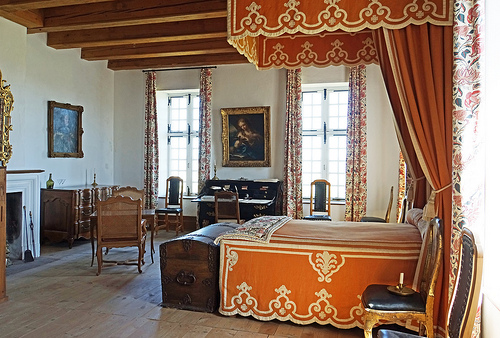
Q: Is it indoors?
A: Yes, it is indoors.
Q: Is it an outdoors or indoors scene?
A: It is indoors.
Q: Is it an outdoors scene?
A: No, it is indoors.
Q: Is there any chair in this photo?
A: Yes, there is a chair.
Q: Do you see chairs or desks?
A: Yes, there is a chair.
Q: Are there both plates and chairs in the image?
A: No, there is a chair but no plates.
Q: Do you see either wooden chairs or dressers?
A: Yes, there is a wood chair.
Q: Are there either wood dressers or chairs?
A: Yes, there is a wood chair.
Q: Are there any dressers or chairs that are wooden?
A: Yes, the chair is wooden.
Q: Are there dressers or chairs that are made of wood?
A: Yes, the chair is made of wood.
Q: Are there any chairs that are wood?
A: Yes, there is a wood chair.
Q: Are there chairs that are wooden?
A: Yes, there is a chair that is wooden.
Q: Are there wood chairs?
A: Yes, there is a chair that is made of wood.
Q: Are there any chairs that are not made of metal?
A: Yes, there is a chair that is made of wood.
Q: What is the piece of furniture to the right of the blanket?
A: The piece of furniture is a chair.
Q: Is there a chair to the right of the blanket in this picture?
A: Yes, there is a chair to the right of the blanket.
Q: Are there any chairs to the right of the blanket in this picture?
A: Yes, there is a chair to the right of the blanket.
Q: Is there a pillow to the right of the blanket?
A: No, there is a chair to the right of the blanket.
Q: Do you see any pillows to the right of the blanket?
A: No, there is a chair to the right of the blanket.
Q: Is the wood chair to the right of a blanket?
A: Yes, the chair is to the right of a blanket.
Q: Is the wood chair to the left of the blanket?
A: No, the chair is to the right of the blanket.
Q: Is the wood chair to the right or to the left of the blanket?
A: The chair is to the right of the blanket.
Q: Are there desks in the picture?
A: Yes, there is a desk.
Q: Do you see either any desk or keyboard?
A: Yes, there is a desk.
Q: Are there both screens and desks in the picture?
A: No, there is a desk but no screens.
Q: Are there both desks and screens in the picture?
A: No, there is a desk but no screens.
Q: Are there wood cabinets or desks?
A: Yes, there is a wood desk.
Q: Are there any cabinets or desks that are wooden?
A: Yes, the desk is wooden.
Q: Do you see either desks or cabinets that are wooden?
A: Yes, the desk is wooden.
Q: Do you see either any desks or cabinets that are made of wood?
A: Yes, the desk is made of wood.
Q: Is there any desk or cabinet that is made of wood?
A: Yes, the desk is made of wood.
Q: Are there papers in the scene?
A: No, there are no papers.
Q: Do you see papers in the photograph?
A: No, there are no papers.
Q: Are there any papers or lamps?
A: No, there are no papers or lamps.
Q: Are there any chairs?
A: Yes, there is a chair.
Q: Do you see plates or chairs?
A: Yes, there is a chair.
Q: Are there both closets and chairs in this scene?
A: No, there is a chair but no closets.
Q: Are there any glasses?
A: No, there are no glasses.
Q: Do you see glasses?
A: No, there are no glasses.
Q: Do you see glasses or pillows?
A: No, there are no glasses or pillows.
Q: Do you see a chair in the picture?
A: Yes, there is a chair.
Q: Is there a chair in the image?
A: Yes, there is a chair.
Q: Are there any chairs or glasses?
A: Yes, there is a chair.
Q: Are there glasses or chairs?
A: Yes, there is a chair.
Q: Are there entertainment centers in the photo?
A: No, there are no entertainment centers.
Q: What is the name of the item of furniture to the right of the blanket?
A: The piece of furniture is a chair.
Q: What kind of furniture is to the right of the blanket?
A: The piece of furniture is a chair.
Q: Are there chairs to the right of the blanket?
A: Yes, there is a chair to the right of the blanket.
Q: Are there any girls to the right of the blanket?
A: No, there is a chair to the right of the blanket.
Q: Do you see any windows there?
A: Yes, there are windows.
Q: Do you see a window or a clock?
A: Yes, there are windows.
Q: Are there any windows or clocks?
A: Yes, there are windows.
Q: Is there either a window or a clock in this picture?
A: Yes, there are windows.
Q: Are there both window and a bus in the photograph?
A: No, there are windows but no buses.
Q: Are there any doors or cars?
A: No, there are no cars or doors.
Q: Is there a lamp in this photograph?
A: No, there are no lamps.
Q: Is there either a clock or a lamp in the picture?
A: No, there are no lamps or clocks.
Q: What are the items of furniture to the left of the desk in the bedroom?
A: The pieces of furniture are chairs.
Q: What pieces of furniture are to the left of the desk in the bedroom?
A: The pieces of furniture are chairs.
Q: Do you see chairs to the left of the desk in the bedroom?
A: Yes, there are chairs to the left of the desk.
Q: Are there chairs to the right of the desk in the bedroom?
A: No, the chairs are to the left of the desk.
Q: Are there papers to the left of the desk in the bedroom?
A: No, there are chairs to the left of the desk.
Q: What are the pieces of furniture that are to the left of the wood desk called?
A: The pieces of furniture are chairs.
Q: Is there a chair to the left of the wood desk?
A: Yes, there are chairs to the left of the desk.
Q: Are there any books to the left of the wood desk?
A: No, there are chairs to the left of the desk.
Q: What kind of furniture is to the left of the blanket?
A: The pieces of furniture are chairs.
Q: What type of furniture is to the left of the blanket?
A: The pieces of furniture are chairs.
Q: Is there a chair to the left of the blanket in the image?
A: Yes, there are chairs to the left of the blanket.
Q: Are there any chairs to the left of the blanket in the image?
A: Yes, there are chairs to the left of the blanket.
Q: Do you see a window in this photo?
A: Yes, there is a window.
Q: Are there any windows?
A: Yes, there is a window.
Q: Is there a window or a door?
A: Yes, there is a window.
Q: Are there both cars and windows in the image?
A: No, there is a window but no cars.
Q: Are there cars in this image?
A: No, there are no cars.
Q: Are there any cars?
A: No, there are no cars.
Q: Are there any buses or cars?
A: No, there are no cars or buses.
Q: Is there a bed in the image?
A: Yes, there is a bed.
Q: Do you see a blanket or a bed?
A: Yes, there is a bed.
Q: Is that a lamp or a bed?
A: That is a bed.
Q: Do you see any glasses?
A: No, there are no glasses.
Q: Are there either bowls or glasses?
A: No, there are no glasses or bowls.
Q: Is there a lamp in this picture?
A: No, there are no lamps.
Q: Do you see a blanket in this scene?
A: Yes, there is a blanket.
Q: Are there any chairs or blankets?
A: Yes, there is a blanket.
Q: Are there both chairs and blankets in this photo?
A: Yes, there are both a blanket and a chair.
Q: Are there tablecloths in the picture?
A: No, there are no tablecloths.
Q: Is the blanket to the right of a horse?
A: No, the blanket is to the right of the chair.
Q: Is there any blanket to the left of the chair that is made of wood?
A: Yes, there is a blanket to the left of the chair.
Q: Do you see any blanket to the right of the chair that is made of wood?
A: No, the blanket is to the left of the chair.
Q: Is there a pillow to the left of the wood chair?
A: No, there is a blanket to the left of the chair.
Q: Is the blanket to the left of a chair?
A: Yes, the blanket is to the left of a chair.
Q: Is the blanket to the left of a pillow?
A: No, the blanket is to the left of a chair.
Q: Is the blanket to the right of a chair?
A: No, the blanket is to the left of a chair.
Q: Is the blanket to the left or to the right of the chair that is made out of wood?
A: The blanket is to the left of the chair.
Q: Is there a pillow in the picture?
A: No, there are no pillows.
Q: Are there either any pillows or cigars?
A: No, there are no pillows or cigars.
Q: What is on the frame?
A: The painting is on the frame.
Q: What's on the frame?
A: The painting is on the frame.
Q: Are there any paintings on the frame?
A: Yes, there is a painting on the frame.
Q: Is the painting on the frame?
A: Yes, the painting is on the frame.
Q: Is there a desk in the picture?
A: Yes, there is a desk.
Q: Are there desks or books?
A: Yes, there is a desk.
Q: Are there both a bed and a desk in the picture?
A: Yes, there are both a desk and a bed.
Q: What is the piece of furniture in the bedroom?
A: The piece of furniture is a desk.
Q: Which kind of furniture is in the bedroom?
A: The piece of furniture is a desk.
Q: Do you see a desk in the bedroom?
A: Yes, there is a desk in the bedroom.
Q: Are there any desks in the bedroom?
A: Yes, there is a desk in the bedroom.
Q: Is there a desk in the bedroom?
A: Yes, there is a desk in the bedroom.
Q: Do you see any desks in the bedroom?
A: Yes, there is a desk in the bedroom.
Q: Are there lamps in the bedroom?
A: No, there is a desk in the bedroom.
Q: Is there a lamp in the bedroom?
A: No, there is a desk in the bedroom.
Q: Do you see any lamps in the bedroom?
A: No, there is a desk in the bedroom.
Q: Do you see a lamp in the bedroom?
A: No, there is a desk in the bedroom.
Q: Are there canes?
A: No, there are no canes.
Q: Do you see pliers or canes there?
A: No, there are no canes or pliers.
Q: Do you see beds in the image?
A: Yes, there is a bed.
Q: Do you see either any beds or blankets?
A: Yes, there is a bed.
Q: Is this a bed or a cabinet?
A: This is a bed.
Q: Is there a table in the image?
A: Yes, there is a table.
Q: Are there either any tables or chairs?
A: Yes, there is a table.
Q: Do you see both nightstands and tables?
A: No, there is a table but no nightstands.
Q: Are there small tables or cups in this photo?
A: Yes, there is a small table.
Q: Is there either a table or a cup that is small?
A: Yes, the table is small.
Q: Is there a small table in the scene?
A: Yes, there is a small table.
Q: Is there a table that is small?
A: Yes, there is a table that is small.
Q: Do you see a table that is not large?
A: Yes, there is a small table.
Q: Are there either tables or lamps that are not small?
A: No, there is a table but it is small.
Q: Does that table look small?
A: Yes, the table is small.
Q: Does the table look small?
A: Yes, the table is small.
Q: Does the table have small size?
A: Yes, the table is small.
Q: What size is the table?
A: The table is small.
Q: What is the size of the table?
A: The table is small.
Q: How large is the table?
A: The table is small.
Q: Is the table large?
A: No, the table is small.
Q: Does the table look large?
A: No, the table is small.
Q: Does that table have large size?
A: No, the table is small.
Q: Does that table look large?
A: No, the table is small.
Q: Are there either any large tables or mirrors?
A: No, there is a table but it is small.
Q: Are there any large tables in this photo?
A: No, there is a table but it is small.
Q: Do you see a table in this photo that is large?
A: No, there is a table but it is small.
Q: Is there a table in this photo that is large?
A: No, there is a table but it is small.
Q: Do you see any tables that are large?
A: No, there is a table but it is small.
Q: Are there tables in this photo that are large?
A: No, there is a table but it is small.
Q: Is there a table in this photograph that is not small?
A: No, there is a table but it is small.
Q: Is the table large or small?
A: The table is small.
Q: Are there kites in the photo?
A: No, there are no kites.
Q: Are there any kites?
A: No, there are no kites.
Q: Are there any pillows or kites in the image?
A: No, there are no kites or pillows.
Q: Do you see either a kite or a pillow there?
A: No, there are no kites or pillows.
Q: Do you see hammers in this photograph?
A: No, there are no hammers.